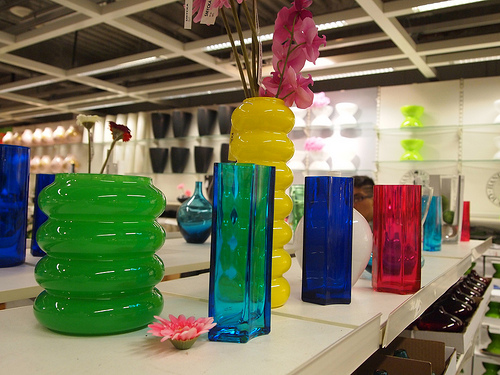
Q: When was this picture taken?
A: It was taken in the day time.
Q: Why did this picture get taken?
A: To show how the vases look.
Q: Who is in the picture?
A: A man is in the picture.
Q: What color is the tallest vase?
A: The tallest vase is yellow.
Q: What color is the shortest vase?
A: The shortest vase is green.